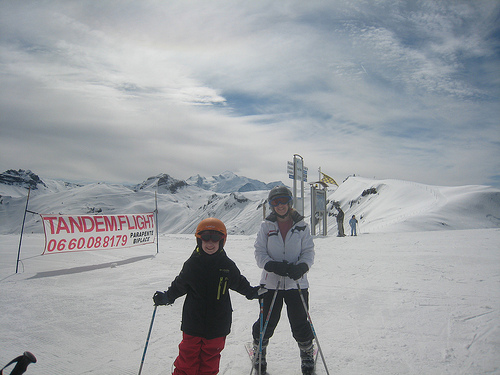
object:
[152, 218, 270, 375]
kid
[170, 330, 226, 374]
pants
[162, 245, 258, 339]
coat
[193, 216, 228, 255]
helmet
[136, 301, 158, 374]
ski pole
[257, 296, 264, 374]
ski pole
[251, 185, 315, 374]
man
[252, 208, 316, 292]
coat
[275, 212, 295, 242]
shirt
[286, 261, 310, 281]
gloves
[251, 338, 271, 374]
ski boot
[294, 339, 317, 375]
ski boot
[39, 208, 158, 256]
banner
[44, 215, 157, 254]
writing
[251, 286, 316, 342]
pants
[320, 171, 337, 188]
flag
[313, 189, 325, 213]
sign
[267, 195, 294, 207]
goggles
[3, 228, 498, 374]
ground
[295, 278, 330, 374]
ski pole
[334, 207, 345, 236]
person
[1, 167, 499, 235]
mountains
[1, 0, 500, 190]
sky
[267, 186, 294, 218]
helmet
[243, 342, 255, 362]
ski